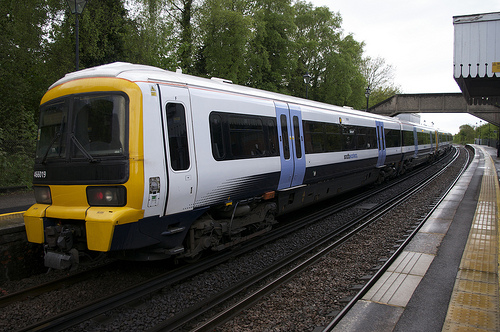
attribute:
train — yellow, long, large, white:
[45, 46, 434, 258]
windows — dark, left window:
[202, 117, 283, 160]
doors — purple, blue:
[270, 97, 310, 182]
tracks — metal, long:
[10, 266, 120, 321]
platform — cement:
[404, 210, 495, 325]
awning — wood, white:
[450, 15, 499, 83]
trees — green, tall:
[3, 5, 119, 169]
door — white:
[141, 77, 210, 209]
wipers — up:
[33, 124, 89, 174]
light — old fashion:
[355, 81, 382, 109]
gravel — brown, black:
[233, 311, 325, 328]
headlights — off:
[24, 186, 138, 221]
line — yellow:
[457, 189, 499, 294]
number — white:
[26, 167, 53, 183]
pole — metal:
[360, 94, 380, 112]